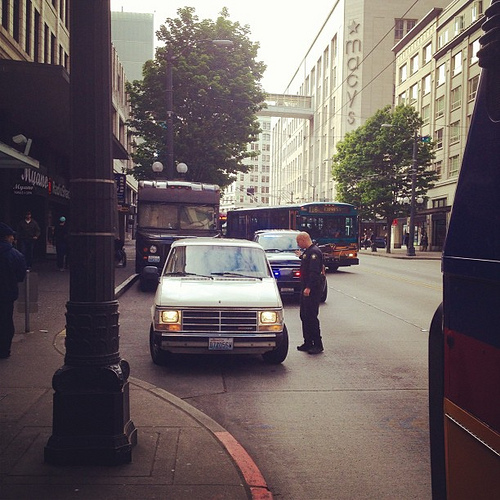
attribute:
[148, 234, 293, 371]
car — discernible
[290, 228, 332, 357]
man — police officer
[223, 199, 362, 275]
bus — citywide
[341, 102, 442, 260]
tree — green, largest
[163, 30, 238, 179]
pole — black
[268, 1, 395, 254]
macy's — store, huge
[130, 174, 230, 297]
truck — blocked, stopped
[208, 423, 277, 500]
paint — red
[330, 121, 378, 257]
tree — smallest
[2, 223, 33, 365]
guy — watching, standing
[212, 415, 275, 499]
curb — red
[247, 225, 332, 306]
car — observed, discernible, silver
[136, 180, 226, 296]
vehicle — ups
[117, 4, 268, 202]
tree — green